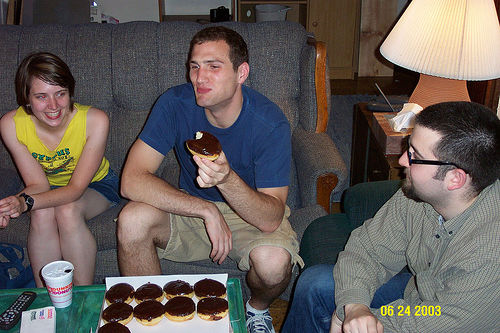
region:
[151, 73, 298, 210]
blue t shirt on man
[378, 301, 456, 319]
yellow stamp date near bottom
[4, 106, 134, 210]
yellow tank top with green lettering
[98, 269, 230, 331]
7 donuts in white tray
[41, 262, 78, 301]
dunkin donuts mug on table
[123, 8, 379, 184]
gray couch with brown wooden frame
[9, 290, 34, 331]
black remote with gray buttons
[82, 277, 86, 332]
green marble table designed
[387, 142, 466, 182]
man with black glasses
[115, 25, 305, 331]
man in a blue t-shirt eating a chocolate covered donut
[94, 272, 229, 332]
a box of chocolate covered donuts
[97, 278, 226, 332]
nine chocolate donuts in a box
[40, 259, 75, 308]
a cup of coffee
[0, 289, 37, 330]
a black remote control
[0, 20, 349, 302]
a man and woman sitting on a blue sofa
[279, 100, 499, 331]
a man wearing eyeglasses sitting in a chair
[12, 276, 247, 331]
a green coffee table in the living room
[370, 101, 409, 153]
a brown box of facial tissue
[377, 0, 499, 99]
a mauve lamp on a wooden table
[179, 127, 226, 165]
Chocolate doughnut in man's hand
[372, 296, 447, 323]
06 24 2003 Yellow date stamp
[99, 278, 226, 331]
Eight chocolate doughnuts in box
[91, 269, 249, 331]
Box holding chocolate doughnuts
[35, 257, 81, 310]
Dunkin donuts cup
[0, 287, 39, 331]
Black remote sitting on table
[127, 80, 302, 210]
Blue shirt man is wearing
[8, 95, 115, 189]
Yellow shirt woman is wearing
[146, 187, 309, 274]
Khaki shorts man is wearing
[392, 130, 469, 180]
Black glasses on man's face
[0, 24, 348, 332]
young man and woman sitting on grey sofa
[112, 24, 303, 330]
man wearing blue t-shirt and eating donut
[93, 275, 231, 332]
donuts in cardboard box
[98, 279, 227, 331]
nine donuts with chocolate frosting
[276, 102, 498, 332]
seated man with black hair wearing glasses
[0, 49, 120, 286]
woman wearing yellow tanktop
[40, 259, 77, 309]
styrofoam coffee cup on green coffee table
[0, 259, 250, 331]
box of donuts, styrofoam cup and remote control on green coffee table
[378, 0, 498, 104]
lamp behind man's head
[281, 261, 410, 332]
right leg of seated man wearing blue jeans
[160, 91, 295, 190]
man in blue shirt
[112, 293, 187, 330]
chocolate donuts in box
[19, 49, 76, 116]
woman with short brown hair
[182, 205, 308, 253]
man in tan shorts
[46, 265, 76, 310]
medium dunkin donuts cup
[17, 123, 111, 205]
woman wearing yellow tank top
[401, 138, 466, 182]
man wearing black glasses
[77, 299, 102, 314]
light and dark green table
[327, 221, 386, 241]
blue cloth sitting chair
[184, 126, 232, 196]
bitten doughnut in mans hand